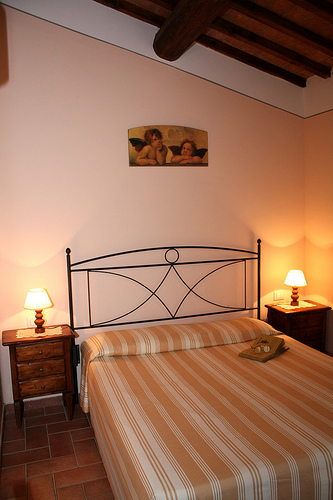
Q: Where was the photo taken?
A: A bedroom.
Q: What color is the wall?
A: White.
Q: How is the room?
A: Well lit.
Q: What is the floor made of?
A: Tiles.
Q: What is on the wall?
A: A piece of art.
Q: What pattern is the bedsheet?
A: Straight lines.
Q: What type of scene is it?
A: Indoor.